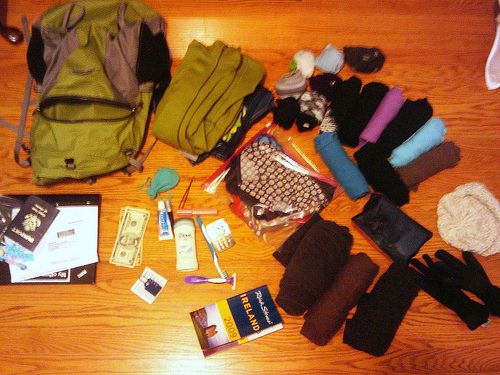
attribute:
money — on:
[104, 205, 152, 268]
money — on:
[114, 205, 141, 270]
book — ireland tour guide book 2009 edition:
[190, 284, 282, 358]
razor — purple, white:
[182, 272, 235, 289]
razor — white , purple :
[178, 269, 243, 291]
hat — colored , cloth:
[430, 188, 497, 253]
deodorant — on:
[159, 203, 212, 283]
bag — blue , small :
[127, 158, 191, 218]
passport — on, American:
[3, 196, 57, 252]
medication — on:
[206, 212, 243, 265]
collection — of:
[270, 65, 463, 356]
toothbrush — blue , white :
[173, 206, 245, 296]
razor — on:
[181, 272, 241, 292]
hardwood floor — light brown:
[1, 1, 498, 373]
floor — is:
[2, 0, 497, 352]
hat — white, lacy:
[435, 180, 499, 256]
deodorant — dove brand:
[173, 215, 198, 273]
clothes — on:
[303, 69, 465, 196]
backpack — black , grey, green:
[32, 7, 152, 189]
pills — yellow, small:
[210, 220, 232, 254]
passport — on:
[4, 199, 63, 247]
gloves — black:
[407, 250, 499, 312]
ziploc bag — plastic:
[231, 141, 329, 228]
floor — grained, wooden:
[4, 290, 192, 374]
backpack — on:
[17, 4, 174, 193]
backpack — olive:
[2, 2, 172, 187]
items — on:
[108, 143, 281, 316]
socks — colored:
[361, 86, 461, 190]